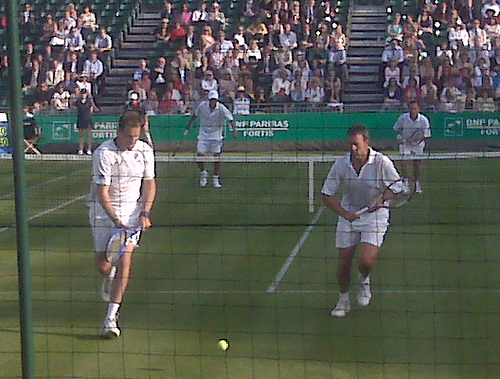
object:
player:
[185, 89, 238, 188]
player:
[392, 100, 432, 193]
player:
[85, 111, 156, 339]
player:
[320, 123, 405, 318]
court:
[1, 149, 499, 378]